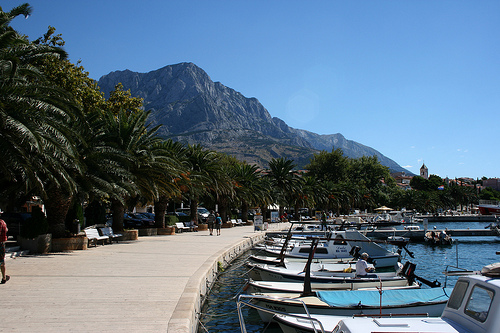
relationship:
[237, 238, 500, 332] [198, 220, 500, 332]
boat in water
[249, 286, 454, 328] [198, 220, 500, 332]
boat in water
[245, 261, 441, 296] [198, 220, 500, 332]
boat in water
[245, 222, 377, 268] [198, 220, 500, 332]
boat in water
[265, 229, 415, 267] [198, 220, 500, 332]
boat in water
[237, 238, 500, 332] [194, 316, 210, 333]
boat held by rope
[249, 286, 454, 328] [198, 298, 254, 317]
boat held by rope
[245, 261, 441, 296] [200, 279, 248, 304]
boat held by rope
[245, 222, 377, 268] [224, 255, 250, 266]
boat held by rope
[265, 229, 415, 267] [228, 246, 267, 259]
boat held by rope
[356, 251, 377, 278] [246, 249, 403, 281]
person sitting on boat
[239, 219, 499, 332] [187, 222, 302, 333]
row tied to wall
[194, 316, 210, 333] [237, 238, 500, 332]
rope on boat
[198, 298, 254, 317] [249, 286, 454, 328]
rope on boat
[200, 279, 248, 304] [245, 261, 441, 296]
rope on boat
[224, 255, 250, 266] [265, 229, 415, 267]
rope on boat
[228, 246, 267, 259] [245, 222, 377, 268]
rope on boat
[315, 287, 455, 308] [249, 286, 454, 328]
cover on top of boat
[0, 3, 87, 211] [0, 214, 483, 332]
tree along sidewalk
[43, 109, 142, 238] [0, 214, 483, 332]
tree along sidewalk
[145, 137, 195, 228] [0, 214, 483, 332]
tree along sidewalk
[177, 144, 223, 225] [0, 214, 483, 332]
tree along sidewalk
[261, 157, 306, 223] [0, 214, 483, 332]
tree along sidewalk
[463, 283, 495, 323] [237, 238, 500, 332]
front window on boat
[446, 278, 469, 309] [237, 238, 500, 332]
front window on boat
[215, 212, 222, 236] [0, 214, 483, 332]
person strolling on sidewalk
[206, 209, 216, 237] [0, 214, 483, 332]
person strolling on sidewalk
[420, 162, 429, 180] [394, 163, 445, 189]
steeple of building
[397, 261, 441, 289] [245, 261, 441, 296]
motor on back of boat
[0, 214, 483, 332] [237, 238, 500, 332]
sidewalk with boat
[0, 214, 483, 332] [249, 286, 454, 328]
sidewalk with boat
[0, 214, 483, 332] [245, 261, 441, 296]
sidewalk with boat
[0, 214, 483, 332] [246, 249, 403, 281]
sidewalk with boat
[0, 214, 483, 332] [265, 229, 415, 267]
sidewalk with boat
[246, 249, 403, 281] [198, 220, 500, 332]
boat in water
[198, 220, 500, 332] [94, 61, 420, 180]
water below moutain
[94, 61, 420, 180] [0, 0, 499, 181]
moutain in front of sky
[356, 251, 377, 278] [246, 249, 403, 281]
person sitting in boat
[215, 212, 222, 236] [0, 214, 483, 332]
person walking on sidewalk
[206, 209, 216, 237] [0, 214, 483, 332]
person walking on sidewalk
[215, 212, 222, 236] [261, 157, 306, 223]
person in front of tree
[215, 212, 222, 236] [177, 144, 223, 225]
person in front of tree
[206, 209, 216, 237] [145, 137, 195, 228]
person in front of tree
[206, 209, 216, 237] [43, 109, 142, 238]
person in front of tree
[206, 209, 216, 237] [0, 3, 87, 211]
person in front of tree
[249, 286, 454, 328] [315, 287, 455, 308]
boat covered in cover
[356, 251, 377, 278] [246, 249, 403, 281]
person sitting inside boat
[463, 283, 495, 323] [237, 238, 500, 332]
front window of boat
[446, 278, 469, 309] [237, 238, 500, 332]
front window of boat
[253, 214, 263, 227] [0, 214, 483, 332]
sign on sidewalk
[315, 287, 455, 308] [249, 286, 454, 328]
cover on boat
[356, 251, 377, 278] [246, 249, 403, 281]
person on boat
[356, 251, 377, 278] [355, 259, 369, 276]
person in shirt